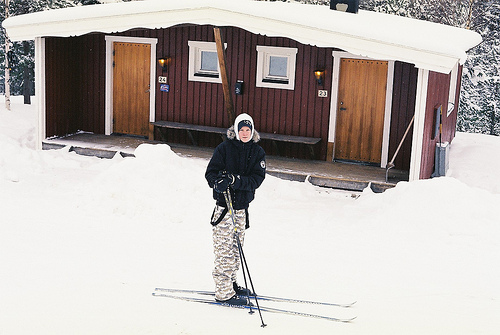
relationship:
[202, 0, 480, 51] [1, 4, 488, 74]
snow on roof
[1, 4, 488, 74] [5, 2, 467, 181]
roof of house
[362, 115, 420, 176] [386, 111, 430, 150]
shovel with handle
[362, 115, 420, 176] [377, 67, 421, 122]
shovel leaning against wall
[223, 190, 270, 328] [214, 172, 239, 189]
ski poles in hands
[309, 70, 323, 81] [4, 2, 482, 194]
light for cabin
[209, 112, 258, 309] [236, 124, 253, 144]
person has face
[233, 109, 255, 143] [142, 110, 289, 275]
head belonging to person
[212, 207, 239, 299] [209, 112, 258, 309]
leg belonging to person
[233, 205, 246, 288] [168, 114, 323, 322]
leg belonging to person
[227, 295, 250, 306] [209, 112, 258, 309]
foot belonging to person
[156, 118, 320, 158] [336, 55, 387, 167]
bench between door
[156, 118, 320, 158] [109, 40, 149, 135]
bench between door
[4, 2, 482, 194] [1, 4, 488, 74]
cabin has roof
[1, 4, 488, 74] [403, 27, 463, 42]
roof has snow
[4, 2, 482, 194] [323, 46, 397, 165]
cabin has door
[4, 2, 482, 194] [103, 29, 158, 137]
cabin has door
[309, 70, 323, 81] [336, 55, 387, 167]
light next to door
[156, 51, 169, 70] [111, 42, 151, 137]
light next to door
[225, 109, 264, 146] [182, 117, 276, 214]
hood on winter jacket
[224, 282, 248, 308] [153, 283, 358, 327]
boots attached to skis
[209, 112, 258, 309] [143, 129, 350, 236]
person in coat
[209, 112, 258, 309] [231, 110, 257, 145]
person in hood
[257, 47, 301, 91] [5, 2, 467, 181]
window on house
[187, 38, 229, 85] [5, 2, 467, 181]
window on house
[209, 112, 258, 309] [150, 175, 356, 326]
person about to go skiing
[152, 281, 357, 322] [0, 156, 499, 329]
skis in snow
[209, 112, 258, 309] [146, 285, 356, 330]
person on skis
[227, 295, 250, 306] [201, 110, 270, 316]
foot on person